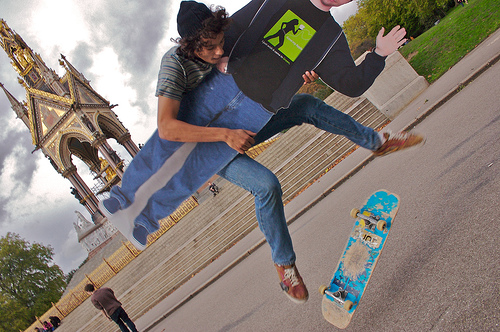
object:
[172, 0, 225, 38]
cap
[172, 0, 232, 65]
head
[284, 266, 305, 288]
lace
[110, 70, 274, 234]
jeans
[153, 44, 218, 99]
shirt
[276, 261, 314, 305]
shoe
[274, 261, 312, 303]
foot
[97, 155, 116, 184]
statue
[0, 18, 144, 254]
monument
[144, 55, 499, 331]
road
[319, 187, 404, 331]
skateboard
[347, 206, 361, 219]
wheel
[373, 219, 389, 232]
wheel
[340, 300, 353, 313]
wheel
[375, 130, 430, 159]
shoe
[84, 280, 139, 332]
man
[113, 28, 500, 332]
pavement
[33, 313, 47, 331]
post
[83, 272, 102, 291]
post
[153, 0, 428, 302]
man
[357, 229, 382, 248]
sign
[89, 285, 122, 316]
shirt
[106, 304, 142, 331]
pants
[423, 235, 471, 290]
cement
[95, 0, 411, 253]
cut out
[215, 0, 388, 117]
shirt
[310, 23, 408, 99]
arm up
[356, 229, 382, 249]
trim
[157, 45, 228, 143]
arm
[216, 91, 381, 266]
jeans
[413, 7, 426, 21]
leaf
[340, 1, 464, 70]
plant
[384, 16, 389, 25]
leaf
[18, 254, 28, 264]
leaf